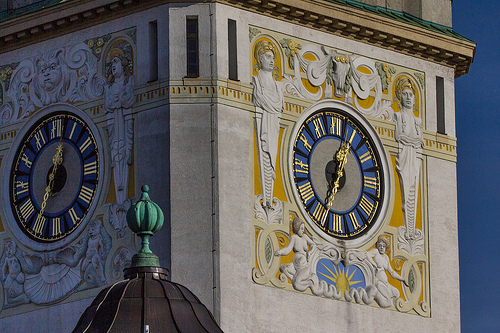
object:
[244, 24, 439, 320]
portrait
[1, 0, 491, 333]
tower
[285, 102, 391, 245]
clock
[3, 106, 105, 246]
clock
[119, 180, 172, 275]
top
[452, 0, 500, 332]
sky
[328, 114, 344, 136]
number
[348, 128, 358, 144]
number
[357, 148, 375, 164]
number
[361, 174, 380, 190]
number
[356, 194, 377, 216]
number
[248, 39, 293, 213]
woman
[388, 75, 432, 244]
woman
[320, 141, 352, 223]
hands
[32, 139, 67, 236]
hands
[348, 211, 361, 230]
number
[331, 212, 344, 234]
number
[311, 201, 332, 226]
number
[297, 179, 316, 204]
number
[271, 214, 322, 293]
statue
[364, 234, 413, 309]
statue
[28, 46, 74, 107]
lion face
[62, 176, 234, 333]
part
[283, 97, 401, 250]
face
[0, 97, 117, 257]
face